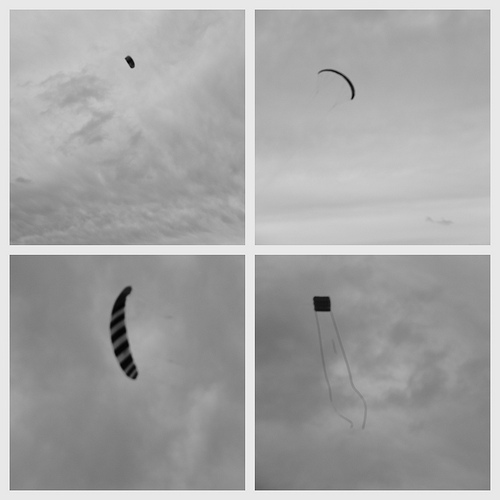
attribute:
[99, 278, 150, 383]
parasail — flying, black, brown, high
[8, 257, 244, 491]
sky — dreary, grey, dark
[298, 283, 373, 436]
kite — square, dark, flying high, flying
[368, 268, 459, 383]
sky — cloudy, dark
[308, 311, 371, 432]
tail — long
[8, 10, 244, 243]
sky — cloudy, dark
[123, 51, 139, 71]
kite — far away, flying high, curved, high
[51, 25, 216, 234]
clouds — thick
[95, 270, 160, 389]
kite — striped, curved, large